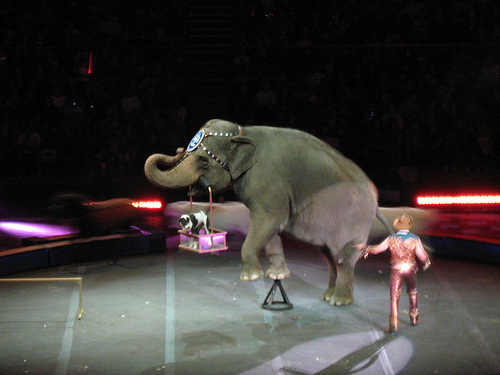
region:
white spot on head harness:
[227, 131, 233, 136]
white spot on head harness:
[218, 130, 223, 137]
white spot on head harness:
[208, 129, 214, 136]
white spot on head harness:
[212, 132, 216, 136]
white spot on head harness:
[214, 156, 220, 161]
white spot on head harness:
[211, 153, 216, 160]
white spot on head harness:
[206, 148, 211, 156]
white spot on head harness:
[201, 143, 206, 152]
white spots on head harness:
[199, 141, 224, 168]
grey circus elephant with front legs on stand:
[130, 100, 375, 309]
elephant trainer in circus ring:
[355, 182, 439, 344]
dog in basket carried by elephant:
[169, 172, 231, 254]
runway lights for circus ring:
[402, 183, 494, 220]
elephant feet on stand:
[237, 242, 295, 287]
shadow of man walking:
[281, 319, 419, 372]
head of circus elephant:
[138, 110, 253, 193]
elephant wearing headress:
[142, 108, 261, 194]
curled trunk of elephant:
[145, 134, 213, 191]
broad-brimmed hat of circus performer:
[391, 209, 416, 240]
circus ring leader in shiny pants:
[350, 203, 432, 340]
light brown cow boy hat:
[387, 209, 418, 233]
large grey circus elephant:
[144, 113, 406, 311]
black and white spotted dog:
[172, 211, 222, 255]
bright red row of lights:
[407, 186, 498, 218]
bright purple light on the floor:
[2, 203, 86, 258]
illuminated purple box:
[172, 216, 230, 261]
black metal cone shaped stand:
[252, 272, 299, 319]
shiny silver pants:
[371, 262, 433, 342]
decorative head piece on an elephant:
[181, 121, 251, 189]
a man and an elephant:
[85, 88, 450, 326]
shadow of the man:
[287, 330, 350, 371]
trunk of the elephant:
[126, 148, 202, 190]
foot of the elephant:
[227, 254, 282, 281]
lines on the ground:
[67, 299, 200, 360]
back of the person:
[375, 194, 435, 337]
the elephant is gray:
[249, 141, 364, 208]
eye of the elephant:
[197, 158, 210, 171]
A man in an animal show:
[0, 0, 498, 374]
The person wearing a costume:
[354, 212, 429, 332]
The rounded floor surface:
[0, 227, 499, 374]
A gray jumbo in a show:
[146, 99, 394, 322]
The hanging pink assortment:
[179, 177, 229, 255]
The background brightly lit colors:
[128, 193, 497, 208]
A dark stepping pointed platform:
[262, 280, 292, 310]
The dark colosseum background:
[0, 0, 499, 217]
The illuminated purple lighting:
[1, 217, 77, 239]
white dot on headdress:
[223, 132, 230, 135]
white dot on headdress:
[211, 130, 221, 134]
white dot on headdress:
[206, 130, 214, 135]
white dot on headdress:
[202, 145, 207, 150]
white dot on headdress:
[206, 148, 211, 157]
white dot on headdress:
[211, 151, 216, 158]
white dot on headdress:
[213, 155, 220, 162]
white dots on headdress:
[201, 139, 226, 166]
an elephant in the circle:
[142, 80, 442, 365]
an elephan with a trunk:
[118, 138, 219, 193]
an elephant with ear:
[232, 128, 249, 173]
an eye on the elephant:
[194, 155, 206, 180]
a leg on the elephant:
[332, 243, 347, 314]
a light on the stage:
[377, 172, 495, 240]